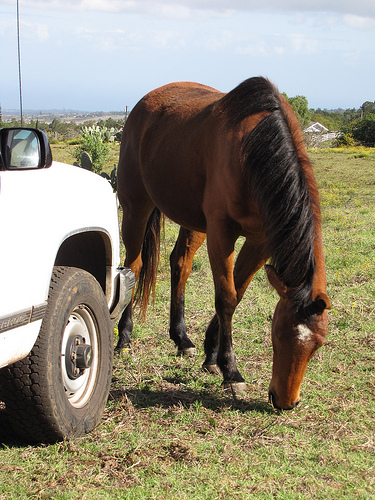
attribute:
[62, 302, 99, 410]
rim — white 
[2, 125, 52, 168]
mirror — black 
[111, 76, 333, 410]
horse — brown 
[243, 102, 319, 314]
mane — black 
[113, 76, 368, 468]
horse — brown 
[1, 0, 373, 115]
sky — blue 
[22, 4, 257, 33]
cloud — white 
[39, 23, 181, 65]
cloud — white 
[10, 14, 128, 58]
cloud — white 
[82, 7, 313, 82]
sky — blue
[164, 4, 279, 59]
clouds — white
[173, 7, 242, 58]
clouds — white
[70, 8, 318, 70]
sky — blue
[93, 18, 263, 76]
sky — blue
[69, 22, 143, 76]
clouds — white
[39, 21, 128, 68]
clouds — white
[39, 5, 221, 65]
sky — blue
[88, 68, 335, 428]
horse — brownish, red